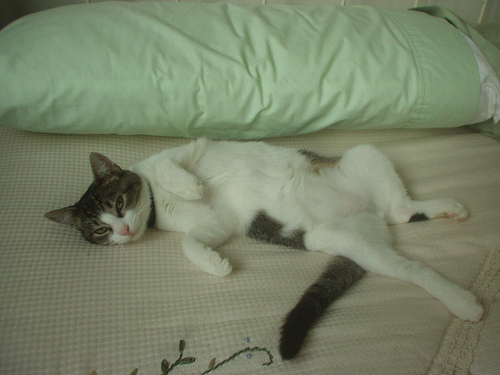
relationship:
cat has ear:
[62, 157, 422, 315] [83, 157, 117, 178]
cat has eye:
[62, 157, 422, 315] [111, 187, 137, 231]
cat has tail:
[62, 157, 422, 315] [266, 272, 344, 330]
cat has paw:
[62, 157, 422, 315] [160, 171, 200, 203]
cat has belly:
[62, 157, 422, 315] [208, 160, 358, 253]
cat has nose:
[62, 157, 422, 315] [113, 221, 143, 235]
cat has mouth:
[62, 157, 422, 315] [138, 224, 156, 250]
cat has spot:
[62, 157, 422, 315] [245, 208, 305, 250]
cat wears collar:
[62, 157, 422, 315] [138, 166, 173, 255]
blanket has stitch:
[64, 300, 135, 335] [153, 356, 239, 372]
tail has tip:
[266, 272, 344, 330] [282, 331, 302, 356]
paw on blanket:
[160, 171, 200, 203] [64, 300, 135, 335]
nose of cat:
[113, 221, 143, 235] [62, 157, 422, 315]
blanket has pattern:
[64, 300, 135, 335] [442, 135, 468, 166]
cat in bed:
[62, 157, 422, 315] [41, 177, 470, 367]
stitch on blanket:
[153, 356, 239, 372] [64, 300, 135, 335]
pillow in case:
[81, 35, 146, 92] [440, 47, 467, 88]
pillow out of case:
[81, 35, 146, 92] [440, 47, 467, 88]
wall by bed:
[465, 11, 488, 19] [41, 177, 470, 367]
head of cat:
[36, 181, 153, 238] [62, 157, 422, 315]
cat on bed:
[62, 157, 422, 315] [41, 177, 470, 367]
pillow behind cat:
[81, 35, 146, 92] [62, 157, 422, 315]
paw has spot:
[160, 171, 200, 203] [245, 208, 305, 250]